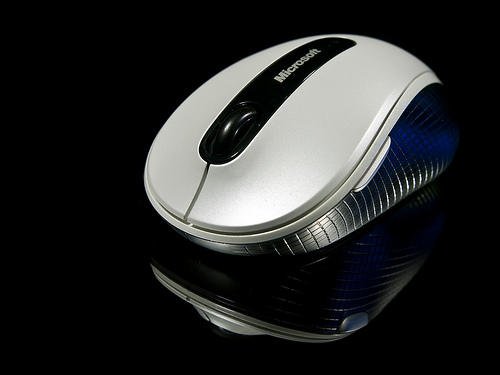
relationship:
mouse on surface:
[124, 25, 482, 263] [5, 104, 500, 340]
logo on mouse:
[266, 43, 330, 92] [124, 25, 482, 263]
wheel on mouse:
[197, 102, 278, 161] [124, 25, 482, 263]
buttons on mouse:
[154, 107, 395, 229] [124, 25, 482, 263]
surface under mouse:
[5, 104, 500, 340] [124, 25, 482, 263]